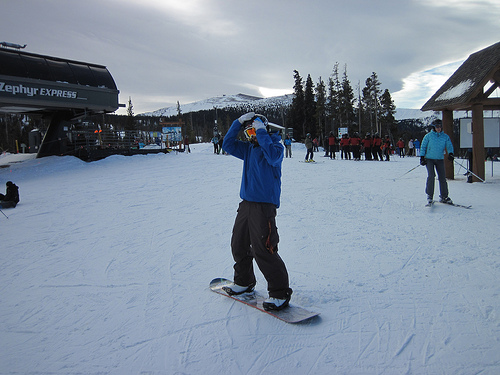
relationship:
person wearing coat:
[225, 110, 291, 307] [223, 124, 282, 204]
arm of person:
[253, 117, 282, 164] [225, 110, 291, 307]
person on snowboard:
[225, 110, 291, 307] [210, 276, 320, 326]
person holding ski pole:
[420, 119, 454, 206] [453, 158, 486, 186]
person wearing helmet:
[225, 110, 291, 307] [243, 116, 264, 135]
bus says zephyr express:
[3, 49, 121, 127] [1, 82, 79, 101]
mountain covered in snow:
[146, 93, 391, 155] [187, 99, 239, 112]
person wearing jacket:
[327, 132, 337, 160] [337, 137, 352, 150]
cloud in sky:
[90, 0, 359, 58] [2, 1, 459, 129]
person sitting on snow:
[3, 177, 19, 208] [1, 133, 499, 375]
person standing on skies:
[420, 119, 454, 206] [425, 197, 471, 214]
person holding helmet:
[225, 110, 291, 307] [243, 116, 264, 135]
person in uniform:
[327, 132, 337, 160] [327, 134, 338, 159]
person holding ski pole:
[420, 119, 454, 206] [402, 161, 427, 179]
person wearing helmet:
[420, 119, 454, 206] [433, 119, 443, 128]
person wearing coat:
[420, 119, 454, 206] [421, 130, 452, 163]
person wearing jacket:
[351, 131, 358, 161] [337, 137, 352, 150]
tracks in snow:
[179, 286, 257, 354] [1, 133, 499, 375]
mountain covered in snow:
[146, 93, 391, 155] [1, 133, 499, 375]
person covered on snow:
[3, 177, 19, 208] [1, 133, 499, 375]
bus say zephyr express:
[3, 49, 121, 127] [1, 82, 79, 101]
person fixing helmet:
[225, 110, 291, 307] [243, 116, 264, 135]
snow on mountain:
[1, 133, 499, 375] [146, 93, 391, 155]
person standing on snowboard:
[225, 110, 291, 307] [210, 276, 320, 326]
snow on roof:
[1, 133, 499, 375] [426, 41, 500, 109]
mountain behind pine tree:
[146, 93, 391, 155] [288, 68, 303, 140]